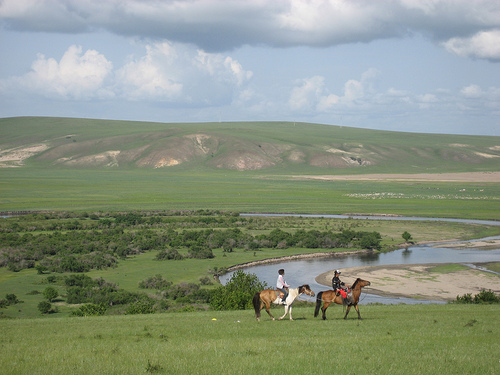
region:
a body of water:
[278, 265, 353, 305]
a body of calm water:
[253, 255, 368, 307]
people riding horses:
[258, 259, 443, 367]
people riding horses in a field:
[248, 250, 480, 372]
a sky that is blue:
[179, 21, 459, 169]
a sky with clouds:
[223, 36, 421, 122]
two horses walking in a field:
[244, 256, 461, 372]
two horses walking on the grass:
[254, 243, 375, 353]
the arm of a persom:
[270, 276, 290, 293]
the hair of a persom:
[270, 265, 288, 281]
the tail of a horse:
[251, 285, 271, 318]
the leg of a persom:
[268, 287, 299, 302]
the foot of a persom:
[276, 295, 297, 310]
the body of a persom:
[273, 260, 301, 298]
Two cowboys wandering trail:
[248, 262, 370, 322]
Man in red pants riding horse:
[313, 266, 370, 320]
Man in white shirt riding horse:
[249, 267, 312, 325]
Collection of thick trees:
[7, 212, 219, 306]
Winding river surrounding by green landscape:
[222, 194, 489, 265]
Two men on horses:
[242, 262, 380, 335]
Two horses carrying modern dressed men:
[244, 261, 373, 329]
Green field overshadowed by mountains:
[36, 108, 479, 216]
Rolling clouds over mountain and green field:
[36, 16, 453, 206]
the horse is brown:
[318, 277, 375, 316]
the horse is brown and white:
[253, 281, 316, 321]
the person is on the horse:
[262, 261, 294, 301]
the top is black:
[330, 277, 344, 292]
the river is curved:
[328, 205, 499, 271]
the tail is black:
[312, 288, 321, 314]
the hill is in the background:
[52, 117, 479, 184]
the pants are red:
[338, 288, 348, 297]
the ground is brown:
[386, 262, 446, 290]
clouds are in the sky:
[171, 1, 448, 61]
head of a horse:
[352, 275, 374, 295]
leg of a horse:
[350, 293, 372, 323]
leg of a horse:
[337, 303, 351, 325]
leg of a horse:
[319, 302, 339, 324]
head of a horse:
[299, 279, 320, 299]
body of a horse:
[306, 282, 351, 312]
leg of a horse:
[263, 302, 281, 323]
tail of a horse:
[243, 298, 258, 323]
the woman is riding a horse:
[275, 268, 290, 303]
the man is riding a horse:
[327, 269, 352, 303]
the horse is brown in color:
[320, 273, 375, 316]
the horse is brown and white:
[253, 282, 312, 321]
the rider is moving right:
[256, 267, 312, 317]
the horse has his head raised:
[351, 275, 371, 290]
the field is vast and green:
[0, 120, 497, 372]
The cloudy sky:
[1, 42, 496, 142]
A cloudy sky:
[0, 42, 498, 134]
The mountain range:
[3, 41, 498, 198]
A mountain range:
[1, 107, 498, 175]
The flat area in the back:
[5, 164, 498, 222]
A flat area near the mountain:
[2, 156, 498, 225]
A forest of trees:
[3, 192, 382, 319]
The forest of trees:
[2, 204, 286, 313]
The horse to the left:
[239, 282, 315, 318]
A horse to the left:
[251, 275, 318, 336]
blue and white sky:
[257, 7, 407, 106]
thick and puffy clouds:
[129, 1, 335, 60]